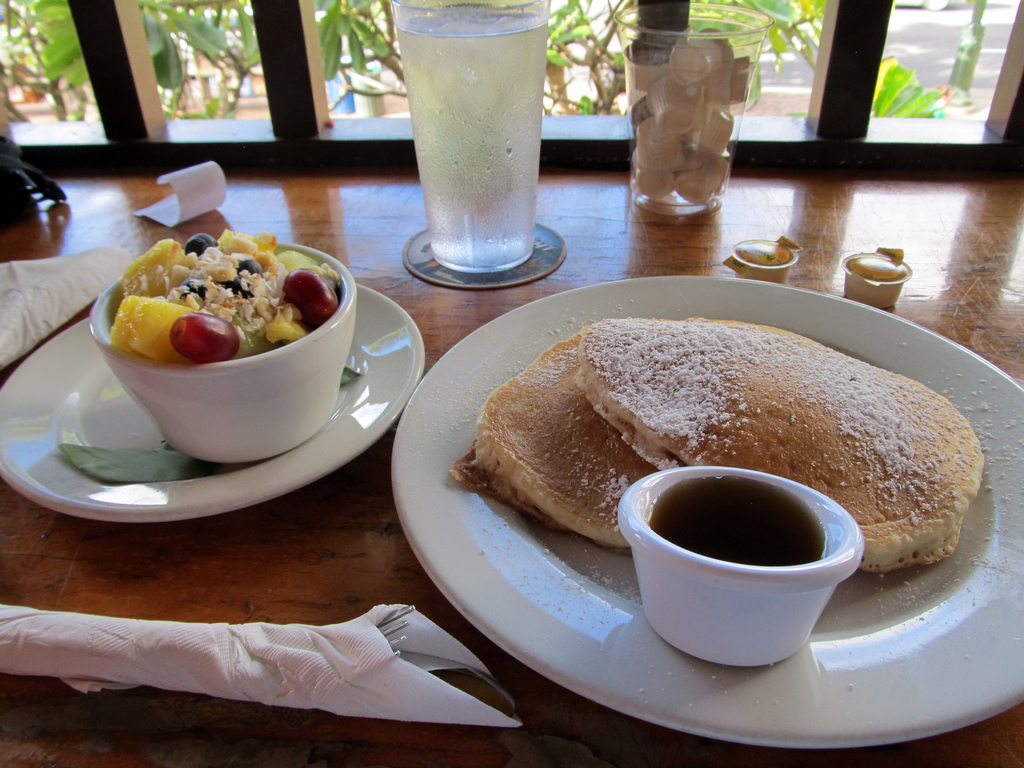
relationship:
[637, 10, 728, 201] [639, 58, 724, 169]
cup filled with cups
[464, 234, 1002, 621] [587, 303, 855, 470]
pancake has powdered sugar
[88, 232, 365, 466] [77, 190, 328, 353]
cup has fruits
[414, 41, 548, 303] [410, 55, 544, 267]
glass has water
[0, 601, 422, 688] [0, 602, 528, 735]
fork in napkin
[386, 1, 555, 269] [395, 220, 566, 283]
glass on coaster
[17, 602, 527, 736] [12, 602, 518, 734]
knife in napkin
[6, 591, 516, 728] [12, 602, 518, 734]
fork in napkin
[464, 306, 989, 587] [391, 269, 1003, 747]
pancakes on plate